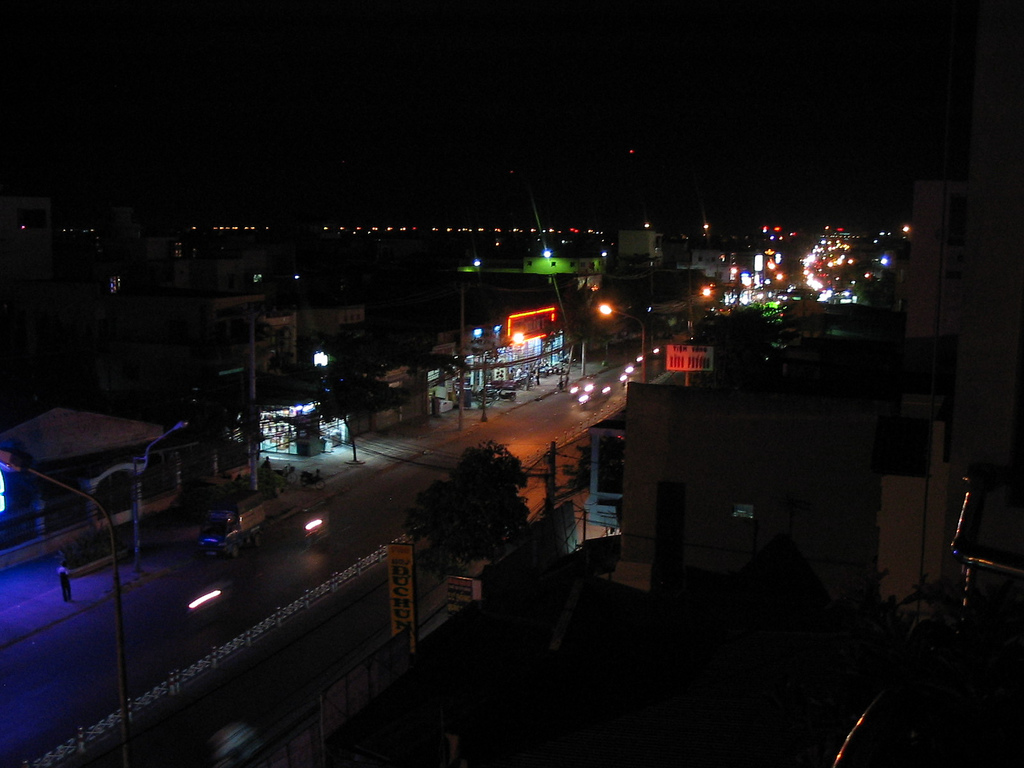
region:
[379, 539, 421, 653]
Yellow sign with black letters.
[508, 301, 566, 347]
Red lit neon sign.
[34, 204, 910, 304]
City lights in the dark.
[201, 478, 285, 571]
Truck is parked on the street.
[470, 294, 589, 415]
Store front with bright lights on.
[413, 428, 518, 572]
Trees near the street.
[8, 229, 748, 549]
Buildings on left side of street.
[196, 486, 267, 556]
a dump truck on the street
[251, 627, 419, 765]
a chain link fence on the sidewalk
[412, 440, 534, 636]
a tree near the sidewalk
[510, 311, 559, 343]
a neon business sign over a building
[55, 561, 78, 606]
a man standing on the sidewalk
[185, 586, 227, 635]
a blur of a motorcycle driving on the street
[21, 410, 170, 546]
a small house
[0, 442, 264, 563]
a fence in front of a house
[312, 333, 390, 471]
tree on the sidewalk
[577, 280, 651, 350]
bright light in city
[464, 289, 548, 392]
bright light in city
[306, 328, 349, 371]
bright light in city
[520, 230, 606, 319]
bright light in city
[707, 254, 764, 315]
bright light in city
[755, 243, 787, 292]
bright light in city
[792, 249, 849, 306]
bright light in city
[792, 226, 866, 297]
bright light in city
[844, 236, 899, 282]
bright light in city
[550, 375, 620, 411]
bright light in city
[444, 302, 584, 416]
white building with lights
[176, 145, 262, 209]
white clouds in the black sky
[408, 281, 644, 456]
building with lights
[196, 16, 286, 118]
black sky with no clouds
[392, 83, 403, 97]
black sky with no clouds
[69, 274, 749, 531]
The buildings to the left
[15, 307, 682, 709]
The black paved road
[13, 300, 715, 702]
A black paved road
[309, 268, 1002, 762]
The buildings to the right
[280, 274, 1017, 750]
A set of buildings to the right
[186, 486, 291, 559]
Truck on the street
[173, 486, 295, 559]
Truck on the road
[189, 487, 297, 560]
Truck near the curb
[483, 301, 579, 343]
Sign on the building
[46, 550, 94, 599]
Person on the sidewalk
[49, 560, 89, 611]
Person near the street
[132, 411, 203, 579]
Street light above truck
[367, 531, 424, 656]
Yellow sign on building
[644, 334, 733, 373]
Sign on the building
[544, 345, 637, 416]
Cars on the road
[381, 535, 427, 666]
A yellow storefront sign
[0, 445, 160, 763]
A streetlight on the road